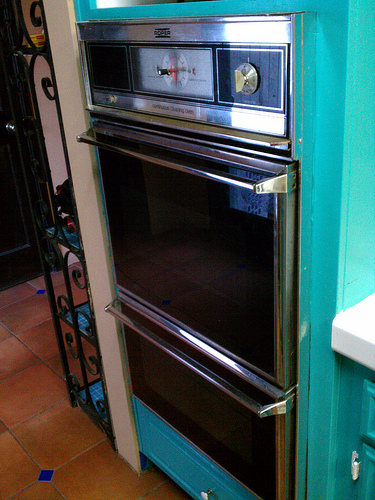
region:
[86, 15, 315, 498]
a built in oven and broiler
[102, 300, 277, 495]
the door to a broiler in and oven set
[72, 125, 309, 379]
the door to a baking oven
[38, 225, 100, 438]
a rod iron shelf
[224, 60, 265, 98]
a temperature control knob for an oven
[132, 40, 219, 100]
the clock for setting the length of time to bake something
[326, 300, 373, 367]
a white counter top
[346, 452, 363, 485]
the hinge to cabinet door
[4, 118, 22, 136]
a door knob of a door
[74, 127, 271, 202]
the handle of an oven door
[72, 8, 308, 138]
operating panel of an oven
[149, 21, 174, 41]
Roper is the brand name of this oven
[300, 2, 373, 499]
the kitchen is painted blue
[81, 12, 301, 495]
this is a double oven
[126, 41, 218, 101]
the clock reads 6:00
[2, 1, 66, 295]
the front door is nearby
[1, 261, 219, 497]
the floor of this apartment is brown and blue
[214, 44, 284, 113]
this knob controls the oven temperature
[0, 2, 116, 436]
a knickknack shelf around the corner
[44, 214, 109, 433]
the knickknack shelves are blue mosaic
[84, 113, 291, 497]
double oven doors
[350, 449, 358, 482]
white cabinet hinge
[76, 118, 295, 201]
metal handle on oven door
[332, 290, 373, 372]
white surface counter top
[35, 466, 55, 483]
royal blue accent tile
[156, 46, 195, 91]
red hands on oven timer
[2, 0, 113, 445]
black metal shelf with spiral design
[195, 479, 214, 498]
white drawer pull on cabinet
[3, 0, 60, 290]
large black door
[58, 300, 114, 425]
blue tile on black shelf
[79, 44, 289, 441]
Oven with glass door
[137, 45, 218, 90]
clock on a oven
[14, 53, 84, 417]
shelf in the kitchen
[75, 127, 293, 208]
Stove with chrome handle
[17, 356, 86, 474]
floor with brown tile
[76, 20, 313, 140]
stove with a chrome face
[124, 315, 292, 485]
bottom part of a oven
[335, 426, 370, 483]
white handle on a door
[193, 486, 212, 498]
white knob on a door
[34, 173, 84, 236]
items on a shelf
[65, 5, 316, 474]
vintage built in oven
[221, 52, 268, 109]
knob on the oven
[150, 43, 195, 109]
timer on the oven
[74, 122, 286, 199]
handle on the oven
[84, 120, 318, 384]
black and silver oven door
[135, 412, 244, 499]
drawer under the oven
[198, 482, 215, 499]
knob on the drawer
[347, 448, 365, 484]
hinge on cupboard door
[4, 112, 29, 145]
doorknob on a door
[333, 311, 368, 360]
counter top next to oven